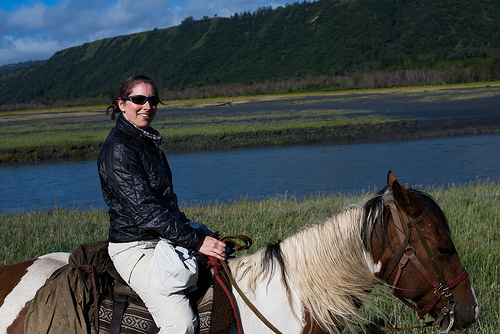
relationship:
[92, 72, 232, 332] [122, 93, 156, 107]
woman wears sunglasses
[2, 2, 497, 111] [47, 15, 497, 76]
mountain covered with trees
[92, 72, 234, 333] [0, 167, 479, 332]
woman riding horse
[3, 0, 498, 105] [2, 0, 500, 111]
trees on mountain